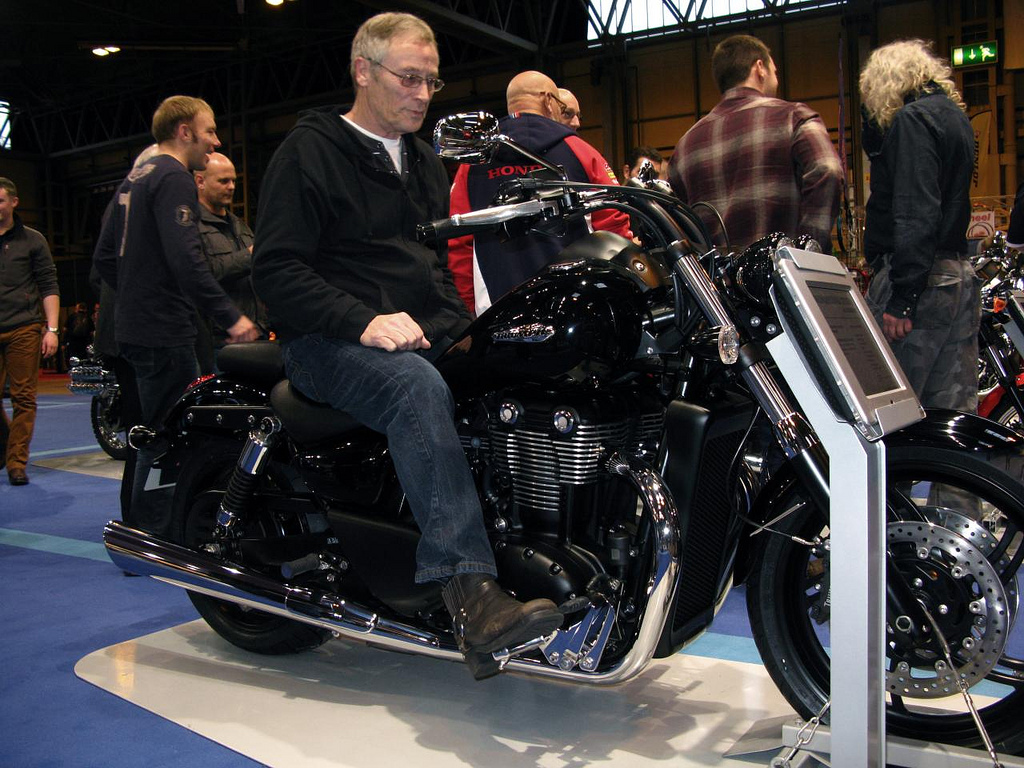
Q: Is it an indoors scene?
A: Yes, it is indoors.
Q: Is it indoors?
A: Yes, it is indoors.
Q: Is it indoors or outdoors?
A: It is indoors.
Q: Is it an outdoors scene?
A: No, it is indoors.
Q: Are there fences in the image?
A: No, there are no fences.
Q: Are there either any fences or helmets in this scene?
A: No, there are no fences or helmets.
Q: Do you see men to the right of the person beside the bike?
A: Yes, there is a man to the right of the person.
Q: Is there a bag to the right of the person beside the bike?
A: No, there is a man to the right of the person.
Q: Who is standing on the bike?
A: The man is standing on the bike.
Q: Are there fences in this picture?
A: No, there are no fences.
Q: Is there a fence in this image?
A: No, there are no fences.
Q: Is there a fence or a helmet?
A: No, there are no fences or helmets.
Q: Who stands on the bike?
A: The man stands on the bike.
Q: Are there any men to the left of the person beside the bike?
A: Yes, there is a man to the left of the person.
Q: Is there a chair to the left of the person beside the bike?
A: No, there is a man to the left of the person.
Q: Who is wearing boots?
A: The man is wearing boots.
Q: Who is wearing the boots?
A: The man is wearing boots.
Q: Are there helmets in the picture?
A: No, there are no helmets.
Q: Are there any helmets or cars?
A: No, there are no helmets or cars.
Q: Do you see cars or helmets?
A: No, there are no helmets or cars.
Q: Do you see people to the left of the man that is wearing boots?
A: Yes, there is a person to the left of the man.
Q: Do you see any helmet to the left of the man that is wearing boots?
A: No, there is a person to the left of the man.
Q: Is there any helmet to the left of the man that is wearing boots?
A: No, there is a person to the left of the man.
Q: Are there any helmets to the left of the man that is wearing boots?
A: No, there is a person to the left of the man.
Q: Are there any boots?
A: Yes, there are boots.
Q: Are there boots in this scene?
A: Yes, there are boots.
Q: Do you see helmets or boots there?
A: Yes, there are boots.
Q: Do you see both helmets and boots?
A: No, there are boots but no helmets.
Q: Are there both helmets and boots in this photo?
A: No, there are boots but no helmets.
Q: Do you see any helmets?
A: No, there are no helmets.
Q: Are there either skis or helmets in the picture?
A: No, there are no helmets or skis.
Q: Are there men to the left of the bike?
A: Yes, there is a man to the left of the bike.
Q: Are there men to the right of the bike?
A: No, the man is to the left of the bike.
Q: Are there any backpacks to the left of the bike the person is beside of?
A: No, there is a man to the left of the bike.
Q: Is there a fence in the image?
A: No, there are no fences.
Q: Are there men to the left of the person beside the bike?
A: Yes, there is a man to the left of the person.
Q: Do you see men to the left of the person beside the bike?
A: Yes, there is a man to the left of the person.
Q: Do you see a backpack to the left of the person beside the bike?
A: No, there is a man to the left of the person.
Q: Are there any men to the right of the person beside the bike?
A: Yes, there is a man to the right of the person.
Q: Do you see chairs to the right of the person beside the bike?
A: No, there is a man to the right of the person.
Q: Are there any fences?
A: No, there are no fences.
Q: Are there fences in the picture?
A: No, there are no fences.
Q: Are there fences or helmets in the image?
A: No, there are no fences or helmets.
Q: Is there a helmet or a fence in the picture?
A: No, there are no fences or helmets.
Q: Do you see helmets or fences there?
A: No, there are no fences or helmets.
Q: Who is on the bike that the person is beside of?
A: The man is on the bike.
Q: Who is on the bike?
A: The man is on the bike.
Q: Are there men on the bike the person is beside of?
A: Yes, there is a man on the bike.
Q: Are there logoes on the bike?
A: No, there is a man on the bike.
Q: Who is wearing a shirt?
A: The man is wearing a shirt.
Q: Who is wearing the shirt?
A: The man is wearing a shirt.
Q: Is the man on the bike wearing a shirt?
A: Yes, the man is wearing a shirt.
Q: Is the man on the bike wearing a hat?
A: No, the man is wearing a shirt.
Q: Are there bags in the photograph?
A: No, there are no bags.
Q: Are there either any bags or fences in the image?
A: No, there are no bags or fences.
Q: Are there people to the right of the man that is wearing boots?
A: Yes, there is a person to the right of the man.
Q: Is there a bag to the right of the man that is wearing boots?
A: No, there is a person to the right of the man.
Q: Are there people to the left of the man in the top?
A: Yes, there is a person to the left of the man.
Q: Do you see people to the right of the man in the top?
A: No, the person is to the left of the man.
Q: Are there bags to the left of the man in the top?
A: No, there is a person to the left of the man.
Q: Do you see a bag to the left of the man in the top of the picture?
A: No, there is a person to the left of the man.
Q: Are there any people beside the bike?
A: Yes, there is a person beside the bike.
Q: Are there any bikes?
A: Yes, there is a bike.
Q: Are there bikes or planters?
A: Yes, there is a bike.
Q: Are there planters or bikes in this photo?
A: Yes, there is a bike.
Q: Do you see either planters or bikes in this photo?
A: Yes, there is a bike.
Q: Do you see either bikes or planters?
A: Yes, there is a bike.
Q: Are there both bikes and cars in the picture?
A: No, there is a bike but no cars.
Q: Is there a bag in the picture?
A: No, there are no bags.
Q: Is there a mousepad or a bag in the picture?
A: No, there are no bags or mouse pads.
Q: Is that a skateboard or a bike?
A: That is a bike.